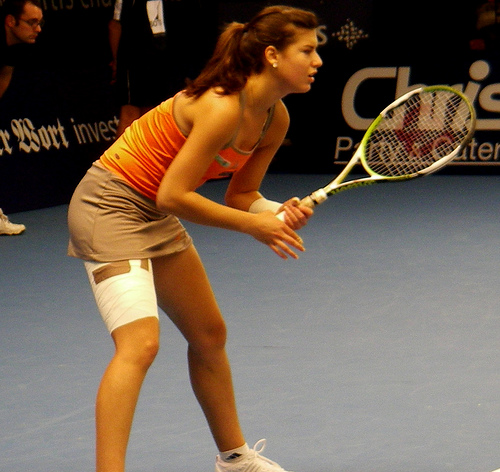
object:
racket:
[277, 81, 473, 225]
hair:
[181, 1, 319, 99]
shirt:
[100, 80, 278, 201]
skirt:
[68, 163, 194, 262]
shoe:
[213, 439, 288, 471]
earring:
[267, 61, 281, 72]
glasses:
[17, 16, 43, 26]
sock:
[215, 442, 258, 464]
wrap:
[94, 262, 162, 334]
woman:
[56, 3, 339, 469]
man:
[0, 0, 46, 234]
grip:
[271, 184, 336, 221]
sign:
[0, 60, 498, 164]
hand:
[248, 209, 301, 261]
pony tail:
[182, 18, 252, 97]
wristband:
[256, 198, 282, 216]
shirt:
[3, 39, 24, 79]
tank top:
[88, 96, 264, 216]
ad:
[0, 113, 120, 156]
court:
[348, 232, 491, 373]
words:
[7, 111, 123, 151]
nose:
[309, 53, 322, 69]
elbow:
[149, 177, 200, 228]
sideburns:
[8, 14, 23, 29]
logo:
[222, 450, 243, 463]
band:
[241, 19, 252, 32]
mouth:
[302, 69, 314, 86]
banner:
[330, 60, 497, 178]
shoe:
[1, 206, 25, 236]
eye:
[300, 43, 316, 59]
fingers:
[265, 243, 289, 263]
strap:
[251, 98, 274, 152]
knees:
[116, 323, 159, 364]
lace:
[245, 436, 278, 469]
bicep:
[175, 140, 221, 176]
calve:
[188, 363, 220, 431]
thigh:
[165, 271, 212, 317]